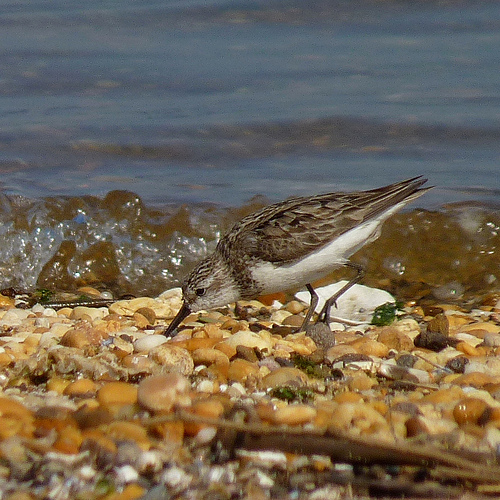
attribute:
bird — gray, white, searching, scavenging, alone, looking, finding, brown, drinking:
[160, 174, 432, 331]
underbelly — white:
[261, 211, 375, 294]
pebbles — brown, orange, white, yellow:
[1, 284, 495, 497]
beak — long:
[162, 302, 195, 339]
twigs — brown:
[213, 411, 485, 495]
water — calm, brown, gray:
[3, 3, 497, 302]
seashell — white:
[296, 277, 399, 331]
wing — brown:
[243, 200, 376, 257]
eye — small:
[191, 282, 208, 299]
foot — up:
[328, 259, 362, 332]